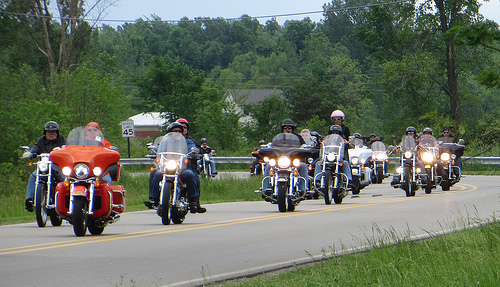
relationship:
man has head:
[23, 118, 65, 211] [43, 120, 59, 139]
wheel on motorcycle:
[74, 199, 84, 234] [47, 127, 125, 233]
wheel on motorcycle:
[277, 180, 287, 210] [256, 129, 312, 212]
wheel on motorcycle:
[322, 170, 329, 201] [256, 129, 312, 212]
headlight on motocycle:
[67, 157, 92, 185] [42, 137, 133, 237]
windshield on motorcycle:
[63, 126, 104, 146] [47, 142, 125, 237]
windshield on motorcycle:
[155, 132, 187, 157] [146, 144, 199, 224]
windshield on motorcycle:
[270, 132, 300, 149] [256, 144, 313, 213]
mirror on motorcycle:
[188, 144, 225, 164] [248, 155, 331, 200]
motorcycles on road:
[34, 103, 459, 234] [5, 172, 484, 273]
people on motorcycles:
[18, 97, 471, 236] [15, 122, 467, 237]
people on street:
[325, 109, 354, 133] [2, 186, 499, 281]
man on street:
[23, 118, 65, 211] [2, 186, 499, 281]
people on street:
[77, 116, 112, 146] [2, 186, 499, 281]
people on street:
[151, 122, 201, 218] [2, 186, 499, 281]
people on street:
[257, 116, 312, 213] [2, 186, 499, 281]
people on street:
[350, 133, 367, 158] [2, 186, 499, 281]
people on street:
[398, 124, 420, 159] [2, 186, 499, 281]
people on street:
[421, 128, 436, 153] [2, 186, 499, 281]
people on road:
[18, 97, 471, 236] [155, 231, 281, 251]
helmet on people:
[326, 110, 342, 120] [52, 100, 359, 170]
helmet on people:
[168, 114, 175, 124] [52, 100, 359, 170]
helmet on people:
[43, 116, 58, 126] [52, 100, 359, 170]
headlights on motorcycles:
[157, 148, 185, 180] [126, 77, 498, 220]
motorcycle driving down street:
[55, 124, 117, 239] [2, 186, 499, 281]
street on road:
[2, 186, 499, 281] [5, 172, 484, 273]